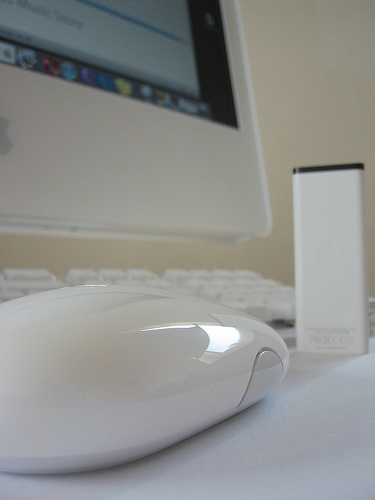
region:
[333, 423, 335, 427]
part of a table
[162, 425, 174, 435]
part of a mouse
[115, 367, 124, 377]
edge of a mouse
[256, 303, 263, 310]
part of a keyboard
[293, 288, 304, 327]
edge of a pole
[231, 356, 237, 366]
side of a mouse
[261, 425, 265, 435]
edge of a table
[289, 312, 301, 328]
edge of a keyboard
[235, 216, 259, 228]
edge of a screen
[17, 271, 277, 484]
a white mouse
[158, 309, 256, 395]
a reflection on the mouse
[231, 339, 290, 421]
a button on the mouse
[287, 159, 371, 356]
a black and white box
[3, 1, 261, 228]
a computer screen on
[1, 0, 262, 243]
a white computer screen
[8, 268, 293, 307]
a white key board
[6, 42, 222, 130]
task bar on screen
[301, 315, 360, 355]
writing on a white box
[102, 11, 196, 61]
a blue line on the screen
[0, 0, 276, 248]
a white iMac computer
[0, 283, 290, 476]
a white Apple Mighty Mouse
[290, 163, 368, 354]
back of a white Apple remote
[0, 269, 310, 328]
a white Apple USB keyboard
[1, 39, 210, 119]
Apple Mac OS X dock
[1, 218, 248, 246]
computer speaker grille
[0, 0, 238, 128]
computer monitor screen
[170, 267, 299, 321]
white numeric keypad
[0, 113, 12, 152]
partial grey Apple logo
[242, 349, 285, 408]
grey mouse hold drag button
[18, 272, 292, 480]
The mouse is white.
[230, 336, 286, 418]
The button is white.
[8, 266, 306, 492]
The mouse is on the table.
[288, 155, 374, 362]
The speaker is white.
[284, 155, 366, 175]
The speaker top is black.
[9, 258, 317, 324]
The keyboard is white.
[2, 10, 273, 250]
The monitor is white.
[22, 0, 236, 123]
The monitor is on.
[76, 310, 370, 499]
The table is white.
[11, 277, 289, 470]
The mouse is shiny.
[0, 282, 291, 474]
white apple mouse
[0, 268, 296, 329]
white mechanical keyboard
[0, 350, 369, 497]
plain white desk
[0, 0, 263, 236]
white early 2000s iMac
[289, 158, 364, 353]
white cylinder electric object with black top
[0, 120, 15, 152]
apple macintosh computer logo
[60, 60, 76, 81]
safari app Macintosh icon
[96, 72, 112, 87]
Microsoft word app icon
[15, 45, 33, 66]
preview Macintosh app icon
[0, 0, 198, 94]
safari app Macintosh window